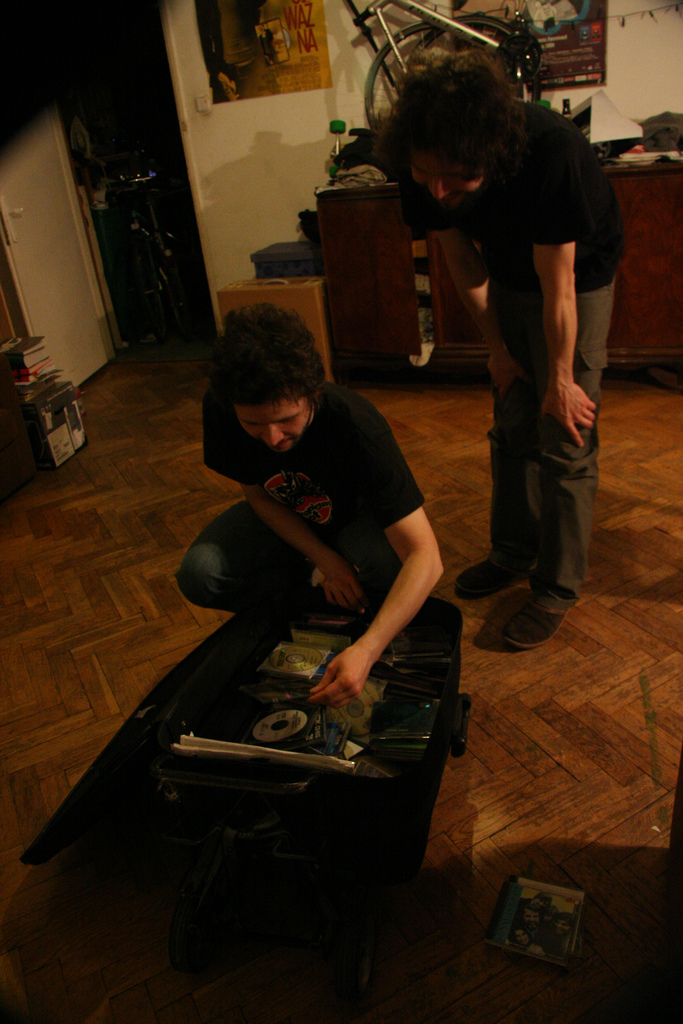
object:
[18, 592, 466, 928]
luggage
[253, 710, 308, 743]
cd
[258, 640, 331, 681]
cd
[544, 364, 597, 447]
hand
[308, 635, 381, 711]
hand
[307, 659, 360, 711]
fingers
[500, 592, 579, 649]
shoe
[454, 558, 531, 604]
shoe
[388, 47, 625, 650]
man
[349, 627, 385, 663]
wrist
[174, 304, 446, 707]
man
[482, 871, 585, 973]
cd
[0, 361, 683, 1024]
floor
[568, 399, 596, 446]
fingers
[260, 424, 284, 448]
nose